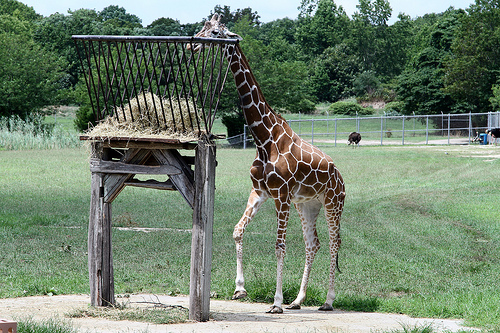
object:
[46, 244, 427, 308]
ground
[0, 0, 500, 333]
photo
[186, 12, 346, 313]
giraffe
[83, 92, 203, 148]
hay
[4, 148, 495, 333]
grass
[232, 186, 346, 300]
legs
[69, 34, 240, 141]
container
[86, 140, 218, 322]
legs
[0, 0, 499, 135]
trees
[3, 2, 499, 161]
background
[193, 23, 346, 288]
spots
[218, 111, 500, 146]
fence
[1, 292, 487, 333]
dirt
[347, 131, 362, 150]
ostrich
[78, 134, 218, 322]
support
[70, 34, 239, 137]
bars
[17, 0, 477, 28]
sky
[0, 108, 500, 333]
enclosure